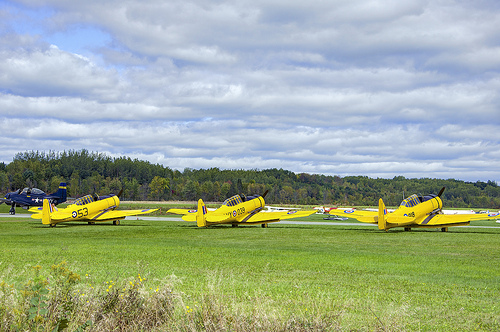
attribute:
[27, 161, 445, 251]
planes — yellow, parked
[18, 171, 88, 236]
plane — dark blue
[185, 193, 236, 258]
tail — yellow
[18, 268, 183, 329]
plants — natural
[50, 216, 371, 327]
field — grassy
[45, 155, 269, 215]
forest — dense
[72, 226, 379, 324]
field — grassy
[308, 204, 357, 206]
sticker — red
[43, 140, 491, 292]
airplanes — yellow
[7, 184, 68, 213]
airplane — blue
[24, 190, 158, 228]
airplane — yellow, single prop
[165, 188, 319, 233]
airplane — yellow, single prop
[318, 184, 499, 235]
airplane — yellow, single prop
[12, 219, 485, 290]
lawn — green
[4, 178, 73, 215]
airplane — dark blue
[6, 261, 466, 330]
grass — tall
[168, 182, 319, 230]
plane — yellow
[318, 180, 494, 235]
plane — yellow, grounded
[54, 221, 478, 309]
field — green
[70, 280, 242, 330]
weeds — brown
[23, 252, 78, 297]
flowers — yellow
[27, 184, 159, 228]
plane — yellow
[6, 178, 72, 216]
plane — grounded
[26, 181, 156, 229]
plane — grounded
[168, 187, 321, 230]
plane — grounded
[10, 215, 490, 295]
field — grass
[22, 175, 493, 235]
planes — yellow, three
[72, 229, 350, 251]
grass — some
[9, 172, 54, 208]
plane — blue, one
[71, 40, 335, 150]
clouds — white